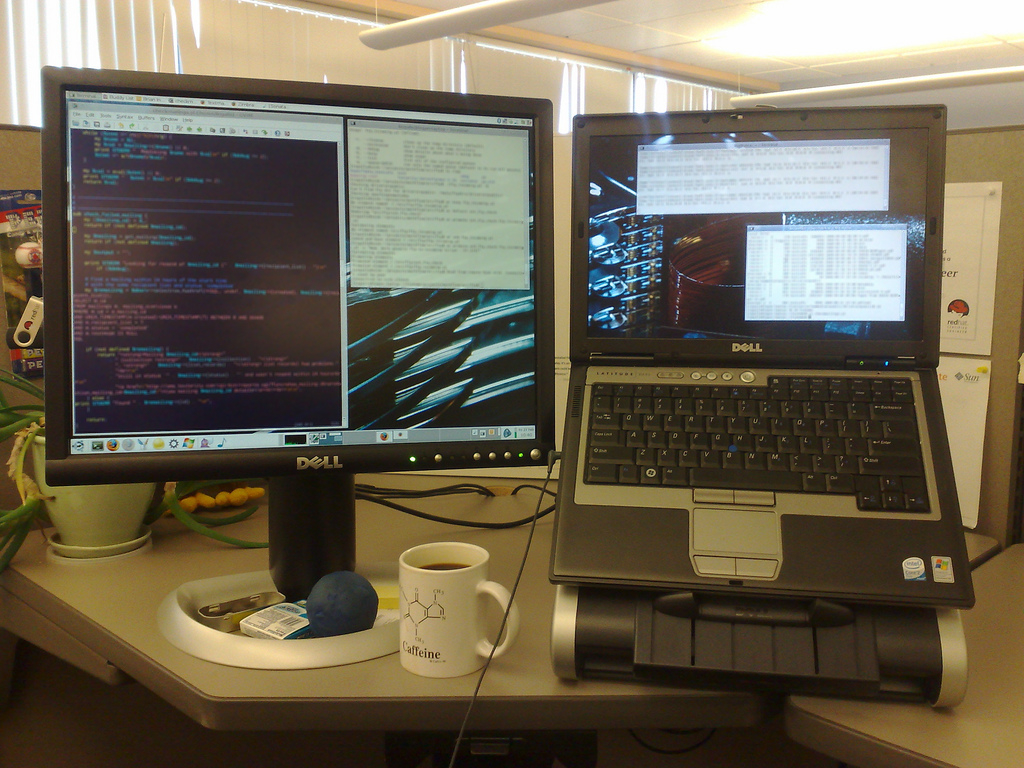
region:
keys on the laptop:
[585, 367, 943, 508]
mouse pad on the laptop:
[672, 495, 799, 550]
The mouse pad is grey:
[680, 500, 794, 565]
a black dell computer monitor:
[24, 32, 595, 532]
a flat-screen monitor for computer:
[19, 49, 611, 553]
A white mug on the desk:
[392, 533, 523, 688]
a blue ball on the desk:
[288, 558, 393, 666]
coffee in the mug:
[413, 547, 471, 577]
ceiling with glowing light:
[383, 7, 1020, 113]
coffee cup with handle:
[395, 542, 517, 678]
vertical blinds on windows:
[6, 0, 744, 118]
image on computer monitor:
[44, 67, 556, 482]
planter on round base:
[31, 427, 156, 564]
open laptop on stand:
[552, 105, 974, 707]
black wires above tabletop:
[357, 481, 553, 530]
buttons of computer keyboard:
[582, 377, 924, 510]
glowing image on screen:
[588, 125, 933, 332]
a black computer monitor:
[42, 60, 559, 503]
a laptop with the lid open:
[570, 117, 970, 607]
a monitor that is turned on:
[46, 70, 550, 457]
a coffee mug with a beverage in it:
[384, 541, 525, 679]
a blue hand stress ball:
[307, 568, 377, 642]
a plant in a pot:
[10, 369, 188, 562]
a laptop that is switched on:
[570, 113, 963, 598]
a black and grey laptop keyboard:
[570, 364, 938, 527]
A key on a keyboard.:
[618, 409, 641, 426]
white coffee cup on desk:
[392, 532, 526, 681]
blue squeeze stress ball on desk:
[296, 565, 383, 639]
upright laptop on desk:
[540, 95, 984, 615]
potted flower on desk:
[2, 354, 272, 598]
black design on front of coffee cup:
[395, 575, 454, 665]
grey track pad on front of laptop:
[683, 500, 788, 565]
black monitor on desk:
[31, 58, 563, 678]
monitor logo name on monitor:
[285, 451, 352, 477]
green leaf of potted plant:
[152, 477, 273, 560]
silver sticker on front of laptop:
[926, 547, 962, 592]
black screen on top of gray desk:
[37, 61, 562, 615]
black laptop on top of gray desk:
[552, 104, 980, 608]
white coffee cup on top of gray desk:
[391, 540, 522, 680]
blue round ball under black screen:
[308, 569, 382, 639]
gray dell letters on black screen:
[293, 447, 352, 477]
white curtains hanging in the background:
[1, 1, 764, 142]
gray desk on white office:
[1, 463, 1014, 764]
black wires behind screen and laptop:
[353, 478, 559, 529]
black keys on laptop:
[589, 377, 923, 508]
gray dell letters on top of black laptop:
[723, 336, 768, 360]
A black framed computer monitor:
[38, 63, 560, 485]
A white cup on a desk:
[392, 543, 514, 683]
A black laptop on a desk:
[548, 107, 972, 607]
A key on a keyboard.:
[661, 411, 684, 441]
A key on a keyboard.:
[679, 406, 709, 435]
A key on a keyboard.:
[717, 411, 746, 434]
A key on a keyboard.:
[740, 411, 770, 437]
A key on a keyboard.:
[765, 411, 789, 434]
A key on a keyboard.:
[789, 412, 812, 435]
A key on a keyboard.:
[777, 425, 809, 452]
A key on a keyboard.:
[764, 443, 791, 466]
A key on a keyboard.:
[720, 444, 740, 464]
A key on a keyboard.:
[632, 441, 655, 462]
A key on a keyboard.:
[623, 422, 649, 449]